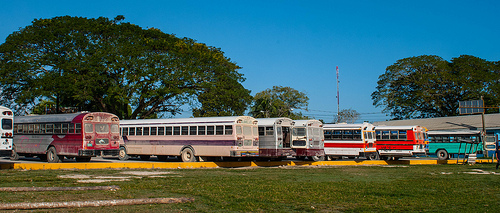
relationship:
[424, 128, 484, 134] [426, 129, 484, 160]
top covering bus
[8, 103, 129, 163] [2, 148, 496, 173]
school bus on parking lot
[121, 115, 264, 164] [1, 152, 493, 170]
bus on parking lot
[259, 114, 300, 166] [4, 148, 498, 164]
school bus on parking lot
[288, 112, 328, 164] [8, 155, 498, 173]
school bus on parking lot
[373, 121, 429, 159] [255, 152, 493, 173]
school bus on parking lot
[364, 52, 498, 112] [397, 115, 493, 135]
tree behind building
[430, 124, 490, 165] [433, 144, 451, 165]
bus has tire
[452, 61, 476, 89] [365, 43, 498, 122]
leaves on tree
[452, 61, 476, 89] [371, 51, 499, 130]
leaves on tree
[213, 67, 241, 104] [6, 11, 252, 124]
leaves on tree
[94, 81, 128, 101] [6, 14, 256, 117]
leaves on tree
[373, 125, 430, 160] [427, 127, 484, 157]
school bus next to one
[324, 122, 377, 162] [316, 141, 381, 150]
bus with stripe